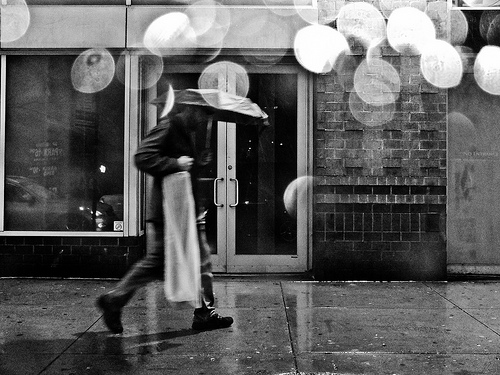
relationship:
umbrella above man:
[146, 83, 267, 130] [102, 96, 237, 374]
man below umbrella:
[102, 96, 237, 374] [146, 83, 267, 130]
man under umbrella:
[102, 96, 237, 374] [146, 83, 267, 130]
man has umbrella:
[102, 96, 237, 374] [146, 83, 267, 130]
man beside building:
[102, 96, 237, 374] [2, 5, 497, 278]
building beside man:
[2, 5, 497, 278] [102, 96, 237, 374]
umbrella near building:
[146, 83, 267, 130] [2, 5, 497, 278]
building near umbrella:
[2, 5, 497, 278] [146, 83, 267, 130]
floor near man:
[3, 274, 499, 370] [102, 96, 237, 374]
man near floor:
[102, 96, 237, 374] [3, 274, 499, 370]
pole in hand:
[194, 118, 221, 186] [169, 149, 196, 175]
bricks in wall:
[327, 58, 442, 187] [322, 19, 455, 277]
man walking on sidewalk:
[102, 96, 237, 374] [2, 282, 484, 372]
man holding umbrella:
[102, 96, 237, 374] [148, 86, 267, 163]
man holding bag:
[102, 96, 237, 374] [163, 171, 202, 308]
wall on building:
[312, 49, 445, 279] [2, 5, 497, 278]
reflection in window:
[2, 173, 115, 230] [3, 53, 122, 230]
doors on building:
[141, 61, 311, 276] [2, 5, 497, 278]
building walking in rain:
[2, 5, 497, 278] [2, 3, 497, 370]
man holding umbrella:
[95, 91, 237, 330] [148, 86, 267, 163]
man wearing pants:
[95, 91, 237, 330] [109, 220, 213, 315]